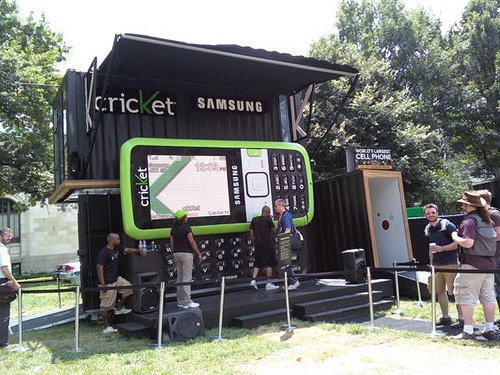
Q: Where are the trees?
A: Behind the stage.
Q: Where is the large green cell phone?
A: On the stage.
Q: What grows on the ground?
A: Grass.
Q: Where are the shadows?
A: In the grass.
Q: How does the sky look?
A: Bright and clear.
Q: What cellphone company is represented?
A: Cricket.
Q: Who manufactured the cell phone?
A: Samsung.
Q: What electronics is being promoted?
A: Cell Phones.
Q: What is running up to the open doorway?
A: A ramp.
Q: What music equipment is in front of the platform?
A: An amplifier.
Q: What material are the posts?
A: Metal.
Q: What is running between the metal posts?
A: A black strap.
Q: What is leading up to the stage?
A: Stairs.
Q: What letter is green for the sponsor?
A: K.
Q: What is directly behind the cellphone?
A: A black building.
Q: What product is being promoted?
A: Cricket Samsung.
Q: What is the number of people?
A: Eight.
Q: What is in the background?
A: Tall trees.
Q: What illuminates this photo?
A: Natural daylight.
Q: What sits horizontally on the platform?
A: A mock cell phone.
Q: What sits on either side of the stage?
A: Speakers.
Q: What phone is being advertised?
A: Cricket.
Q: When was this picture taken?
A: Daytime.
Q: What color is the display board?
A: Black.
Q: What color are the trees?
A: Green.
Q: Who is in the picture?
A: Men and women.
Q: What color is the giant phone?
A: Neon green.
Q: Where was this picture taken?
A: A field.